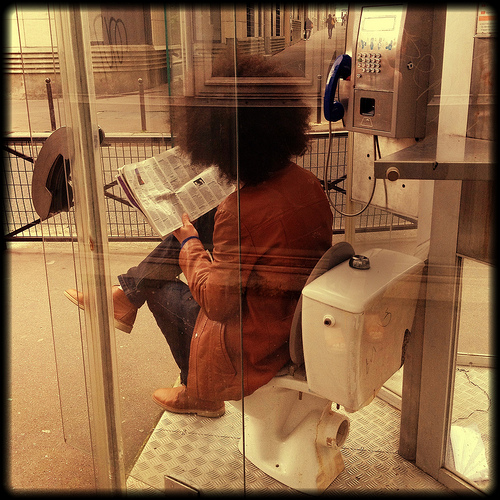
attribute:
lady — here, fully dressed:
[57, 44, 318, 421]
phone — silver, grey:
[311, 3, 428, 134]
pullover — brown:
[177, 178, 314, 409]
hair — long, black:
[166, 53, 305, 180]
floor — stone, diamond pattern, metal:
[136, 383, 439, 488]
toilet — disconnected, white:
[209, 244, 412, 495]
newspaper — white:
[112, 151, 242, 236]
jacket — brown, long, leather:
[170, 176, 325, 405]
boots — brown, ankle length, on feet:
[66, 281, 226, 422]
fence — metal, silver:
[12, 129, 421, 246]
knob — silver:
[349, 249, 372, 272]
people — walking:
[301, 16, 339, 39]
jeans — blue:
[125, 204, 222, 388]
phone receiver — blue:
[317, 54, 352, 120]